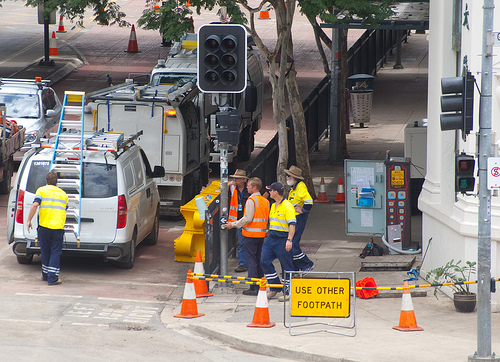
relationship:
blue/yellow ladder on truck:
[43, 89, 85, 248] [23, 148, 116, 252]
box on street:
[344, 155, 420, 252] [7, 303, 165, 357]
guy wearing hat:
[281, 163, 315, 270] [283, 164, 307, 179]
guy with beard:
[281, 163, 317, 277] [282, 173, 302, 187]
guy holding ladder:
[23, 170, 70, 287] [41, 86, 87, 241]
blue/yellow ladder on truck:
[43, 89, 85, 248] [3, 129, 168, 271]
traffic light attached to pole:
[439, 59, 476, 134] [471, 0, 496, 359]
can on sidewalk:
[345, 73, 377, 128] [193, 7, 493, 360]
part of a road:
[103, 254, 193, 305] [0, 0, 365, 360]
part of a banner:
[129, 171, 242, 287] [283, 260, 356, 357]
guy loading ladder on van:
[23, 170, 70, 287] [2, 119, 119, 308]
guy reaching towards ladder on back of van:
[23, 170, 70, 287] [29, 125, 147, 270]